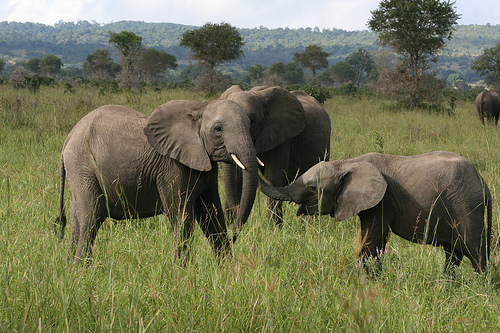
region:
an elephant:
[255, 144, 497, 276]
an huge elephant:
[43, 90, 254, 258]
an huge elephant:
[217, 80, 332, 220]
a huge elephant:
[471, 81, 496, 128]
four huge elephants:
[42, 75, 497, 265]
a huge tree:
[182, 16, 238, 76]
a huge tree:
[366, 1, 451, 96]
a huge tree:
[110, 30, 140, 86]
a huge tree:
[140, 45, 175, 83]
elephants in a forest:
[1, 0, 495, 330]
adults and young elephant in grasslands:
[30, 76, 486, 296]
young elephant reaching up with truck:
[227, 140, 392, 225]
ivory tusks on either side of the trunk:
[211, 115, 271, 181]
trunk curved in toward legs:
[195, 95, 261, 251]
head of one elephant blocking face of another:
[196, 80, 276, 190]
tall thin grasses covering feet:
[35, 220, 442, 317]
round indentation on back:
[387, 131, 478, 196]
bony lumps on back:
[427, 145, 472, 191]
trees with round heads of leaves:
[25, 10, 445, 90]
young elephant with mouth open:
[270, 167, 320, 232]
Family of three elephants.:
[53, 83, 489, 280]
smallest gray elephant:
[251, 148, 491, 278]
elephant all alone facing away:
[475, 86, 498, 123]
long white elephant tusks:
[230, 150, 265, 167]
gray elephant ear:
[142, 97, 209, 169]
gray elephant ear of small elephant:
[330, 161, 386, 221]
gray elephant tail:
[51, 147, 66, 239]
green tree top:
[177, 17, 242, 63]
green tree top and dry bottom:
[366, 0, 454, 108]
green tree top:
[364, 0, 462, 60]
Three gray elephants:
[60, 86, 488, 275]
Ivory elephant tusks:
[230, 146, 266, 170]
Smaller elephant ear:
[336, 162, 385, 223]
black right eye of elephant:
[210, 126, 222, 133]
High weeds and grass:
[250, 231, 342, 316]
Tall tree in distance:
[180, 21, 245, 93]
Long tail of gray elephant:
[48, 151, 68, 238]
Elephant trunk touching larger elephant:
[246, 172, 296, 205]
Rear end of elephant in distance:
[474, 86, 499, 127]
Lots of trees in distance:
[249, 27, 302, 50]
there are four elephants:
[55, 78, 498, 215]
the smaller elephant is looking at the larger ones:
[82, 87, 499, 215]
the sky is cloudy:
[8, 4, 195, 84]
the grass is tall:
[21, 243, 151, 319]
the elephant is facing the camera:
[222, 79, 403, 155]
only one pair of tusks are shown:
[28, 82, 449, 224]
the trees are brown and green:
[80, 21, 453, 138]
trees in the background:
[256, 20, 332, 67]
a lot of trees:
[51, 11, 497, 106]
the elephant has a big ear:
[137, 87, 240, 217]